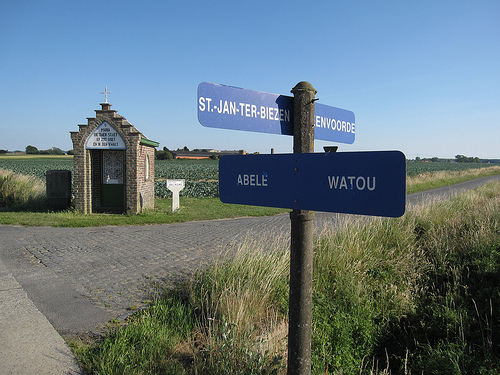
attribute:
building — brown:
[70, 103, 160, 214]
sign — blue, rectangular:
[219, 150, 405, 218]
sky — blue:
[0, 0, 499, 159]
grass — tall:
[66, 176, 500, 374]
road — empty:
[0, 175, 499, 374]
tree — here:
[26, 145, 67, 155]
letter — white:
[328, 176, 341, 191]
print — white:
[328, 174, 378, 191]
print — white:
[199, 97, 212, 113]